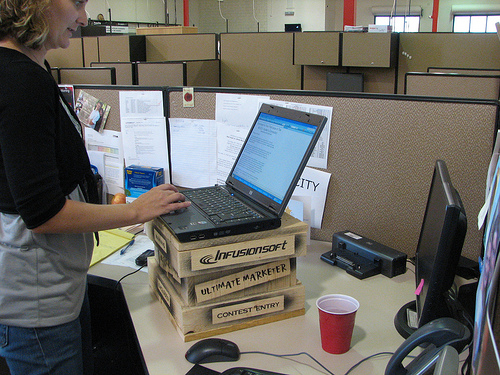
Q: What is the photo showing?
A: It is showing an office.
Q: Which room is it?
A: It is an office.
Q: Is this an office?
A: Yes, it is an office.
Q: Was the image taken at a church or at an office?
A: It was taken at an office.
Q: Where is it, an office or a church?
A: It is an office.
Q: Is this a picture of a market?
A: No, the picture is showing an office.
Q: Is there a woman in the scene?
A: Yes, there is a woman.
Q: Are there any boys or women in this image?
A: Yes, there is a woman.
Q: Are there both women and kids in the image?
A: No, there is a woman but no children.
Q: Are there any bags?
A: No, there are no bags.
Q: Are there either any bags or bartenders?
A: No, there are no bags or bartenders.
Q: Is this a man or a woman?
A: This is a woman.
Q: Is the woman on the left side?
A: Yes, the woman is on the left of the image.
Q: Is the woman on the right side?
A: No, the woman is on the left of the image.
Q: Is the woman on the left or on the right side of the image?
A: The woman is on the left of the image.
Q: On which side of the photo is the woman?
A: The woman is on the left of the image.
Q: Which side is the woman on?
A: The woman is on the left of the image.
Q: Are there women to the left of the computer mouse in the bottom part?
A: Yes, there is a woman to the left of the mouse.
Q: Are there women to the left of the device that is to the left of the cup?
A: Yes, there is a woman to the left of the mouse.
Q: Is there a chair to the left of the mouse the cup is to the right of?
A: No, there is a woman to the left of the computer mouse.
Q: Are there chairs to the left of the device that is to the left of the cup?
A: No, there is a woman to the left of the computer mouse.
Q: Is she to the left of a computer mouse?
A: Yes, the woman is to the left of a computer mouse.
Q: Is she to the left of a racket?
A: No, the woman is to the left of a computer mouse.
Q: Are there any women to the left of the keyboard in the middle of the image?
A: Yes, there is a woman to the left of the keyboard.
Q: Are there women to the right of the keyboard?
A: No, the woman is to the left of the keyboard.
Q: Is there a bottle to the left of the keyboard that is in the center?
A: No, there is a woman to the left of the keyboard.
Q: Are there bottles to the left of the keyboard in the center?
A: No, there is a woman to the left of the keyboard.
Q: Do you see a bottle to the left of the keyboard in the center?
A: No, there is a woman to the left of the keyboard.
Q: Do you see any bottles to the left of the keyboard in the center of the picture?
A: No, there is a woman to the left of the keyboard.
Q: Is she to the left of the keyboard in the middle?
A: Yes, the woman is to the left of the keyboard.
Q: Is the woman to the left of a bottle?
A: No, the woman is to the left of the keyboard.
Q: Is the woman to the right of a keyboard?
A: No, the woman is to the left of a keyboard.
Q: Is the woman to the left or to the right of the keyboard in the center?
A: The woman is to the left of the keyboard.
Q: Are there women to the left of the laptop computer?
A: Yes, there is a woman to the left of the laptop computer.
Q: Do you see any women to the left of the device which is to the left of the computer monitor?
A: Yes, there is a woman to the left of the laptop computer.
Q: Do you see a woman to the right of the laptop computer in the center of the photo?
A: No, the woman is to the left of the laptop.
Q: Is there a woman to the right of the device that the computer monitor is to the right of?
A: No, the woman is to the left of the laptop.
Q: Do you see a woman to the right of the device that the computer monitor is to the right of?
A: No, the woman is to the left of the laptop.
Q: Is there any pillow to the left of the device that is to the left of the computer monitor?
A: No, there is a woman to the left of the laptop.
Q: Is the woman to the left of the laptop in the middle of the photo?
A: Yes, the woman is to the left of the laptop.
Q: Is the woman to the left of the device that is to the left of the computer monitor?
A: Yes, the woman is to the left of the laptop.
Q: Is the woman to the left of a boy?
A: No, the woman is to the left of the laptop.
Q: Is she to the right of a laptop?
A: No, the woman is to the left of a laptop.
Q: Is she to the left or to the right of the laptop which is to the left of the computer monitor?
A: The woman is to the left of the laptop computer.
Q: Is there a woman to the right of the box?
A: No, the woman is to the left of the box.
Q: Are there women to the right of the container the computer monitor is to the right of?
A: No, the woman is to the left of the box.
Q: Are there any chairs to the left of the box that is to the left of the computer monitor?
A: No, there is a woman to the left of the box.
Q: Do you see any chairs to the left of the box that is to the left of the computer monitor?
A: No, there is a woman to the left of the box.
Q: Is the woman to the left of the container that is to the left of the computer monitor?
A: Yes, the woman is to the left of the box.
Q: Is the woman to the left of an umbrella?
A: No, the woman is to the left of the box.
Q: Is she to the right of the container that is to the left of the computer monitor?
A: No, the woman is to the left of the box.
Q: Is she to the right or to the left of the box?
A: The woman is to the left of the box.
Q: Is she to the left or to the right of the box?
A: The woman is to the left of the box.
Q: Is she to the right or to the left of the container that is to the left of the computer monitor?
A: The woman is to the left of the box.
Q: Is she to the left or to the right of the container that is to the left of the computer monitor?
A: The woman is to the left of the box.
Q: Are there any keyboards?
A: Yes, there is a keyboard.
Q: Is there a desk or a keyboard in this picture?
A: Yes, there is a keyboard.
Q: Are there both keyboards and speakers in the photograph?
A: No, there is a keyboard but no speakers.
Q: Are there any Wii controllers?
A: No, there are no Wii controllers.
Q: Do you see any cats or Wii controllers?
A: No, there are no Wii controllers or cats.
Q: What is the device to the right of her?
A: The device is a keyboard.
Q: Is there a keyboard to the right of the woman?
A: Yes, there is a keyboard to the right of the woman.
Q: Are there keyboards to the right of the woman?
A: Yes, there is a keyboard to the right of the woman.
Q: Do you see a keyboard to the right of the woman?
A: Yes, there is a keyboard to the right of the woman.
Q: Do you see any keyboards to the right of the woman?
A: Yes, there is a keyboard to the right of the woman.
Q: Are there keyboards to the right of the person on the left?
A: Yes, there is a keyboard to the right of the woman.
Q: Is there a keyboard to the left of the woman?
A: No, the keyboard is to the right of the woman.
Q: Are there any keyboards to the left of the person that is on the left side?
A: No, the keyboard is to the right of the woman.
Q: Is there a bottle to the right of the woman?
A: No, there is a keyboard to the right of the woman.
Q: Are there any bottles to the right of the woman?
A: No, there is a keyboard to the right of the woman.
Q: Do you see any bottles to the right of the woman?
A: No, there is a keyboard to the right of the woman.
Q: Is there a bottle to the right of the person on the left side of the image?
A: No, there is a keyboard to the right of the woman.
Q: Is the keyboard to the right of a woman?
A: Yes, the keyboard is to the right of a woman.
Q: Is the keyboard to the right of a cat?
A: No, the keyboard is to the right of a woman.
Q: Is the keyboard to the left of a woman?
A: No, the keyboard is to the right of a woman.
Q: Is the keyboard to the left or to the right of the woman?
A: The keyboard is to the right of the woman.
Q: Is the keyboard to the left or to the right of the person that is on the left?
A: The keyboard is to the right of the woman.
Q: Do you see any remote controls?
A: No, there are no remote controls.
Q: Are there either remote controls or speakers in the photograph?
A: No, there are no remote controls or speakers.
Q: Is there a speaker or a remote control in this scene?
A: No, there are no remote controls or speakers.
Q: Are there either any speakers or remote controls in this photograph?
A: No, there are no remote controls or speakers.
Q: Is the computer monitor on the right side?
A: Yes, the computer monitor is on the right of the image.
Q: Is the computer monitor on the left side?
A: No, the computer monitor is on the right of the image.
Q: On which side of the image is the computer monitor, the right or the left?
A: The computer monitor is on the right of the image.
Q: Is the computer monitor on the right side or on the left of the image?
A: The computer monitor is on the right of the image.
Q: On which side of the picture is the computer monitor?
A: The computer monitor is on the right of the image.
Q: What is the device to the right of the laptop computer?
A: The device is a computer monitor.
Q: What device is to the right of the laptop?
A: The device is a computer monitor.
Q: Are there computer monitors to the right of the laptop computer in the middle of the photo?
A: Yes, there is a computer monitor to the right of the laptop.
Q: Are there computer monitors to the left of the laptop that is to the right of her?
A: No, the computer monitor is to the right of the laptop.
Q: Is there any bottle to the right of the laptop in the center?
A: No, there is a computer monitor to the right of the laptop.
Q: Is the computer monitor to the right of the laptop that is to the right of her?
A: Yes, the computer monitor is to the right of the laptop.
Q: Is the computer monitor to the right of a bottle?
A: No, the computer monitor is to the right of the laptop.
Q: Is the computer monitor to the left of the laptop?
A: No, the computer monitor is to the right of the laptop.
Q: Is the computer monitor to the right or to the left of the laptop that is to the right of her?
A: The computer monitor is to the right of the laptop.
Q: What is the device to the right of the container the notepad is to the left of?
A: The device is a computer monitor.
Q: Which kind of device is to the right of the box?
A: The device is a computer monitor.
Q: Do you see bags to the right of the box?
A: No, there is a computer monitor to the right of the box.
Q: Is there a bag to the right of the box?
A: No, there is a computer monitor to the right of the box.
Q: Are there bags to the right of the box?
A: No, there is a computer monitor to the right of the box.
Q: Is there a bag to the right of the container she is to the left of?
A: No, there is a computer monitor to the right of the box.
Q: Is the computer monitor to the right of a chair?
A: No, the computer monitor is to the right of the box.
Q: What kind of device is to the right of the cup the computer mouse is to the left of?
A: The device is a computer monitor.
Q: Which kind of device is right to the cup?
A: The device is a computer monitor.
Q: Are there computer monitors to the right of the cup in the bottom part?
A: Yes, there is a computer monitor to the right of the cup.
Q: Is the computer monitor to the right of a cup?
A: Yes, the computer monitor is to the right of a cup.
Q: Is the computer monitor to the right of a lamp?
A: No, the computer monitor is to the right of a cup.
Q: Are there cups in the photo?
A: Yes, there is a cup.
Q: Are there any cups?
A: Yes, there is a cup.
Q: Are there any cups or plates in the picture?
A: Yes, there is a cup.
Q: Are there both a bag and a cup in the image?
A: No, there is a cup but no bags.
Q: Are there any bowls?
A: No, there are no bowls.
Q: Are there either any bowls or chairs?
A: No, there are no bowls or chairs.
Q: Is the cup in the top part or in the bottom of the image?
A: The cup is in the bottom of the image.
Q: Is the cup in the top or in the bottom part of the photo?
A: The cup is in the bottom of the image.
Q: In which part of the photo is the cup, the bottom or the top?
A: The cup is in the bottom of the image.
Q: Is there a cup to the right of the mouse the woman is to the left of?
A: Yes, there is a cup to the right of the computer mouse.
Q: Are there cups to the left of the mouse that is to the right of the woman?
A: No, the cup is to the right of the computer mouse.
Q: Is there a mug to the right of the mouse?
A: No, there is a cup to the right of the mouse.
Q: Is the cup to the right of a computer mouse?
A: Yes, the cup is to the right of a computer mouse.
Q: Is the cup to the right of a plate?
A: No, the cup is to the right of a computer mouse.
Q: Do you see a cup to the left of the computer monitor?
A: Yes, there is a cup to the left of the computer monitor.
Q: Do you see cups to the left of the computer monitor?
A: Yes, there is a cup to the left of the computer monitor.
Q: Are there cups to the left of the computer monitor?
A: Yes, there is a cup to the left of the computer monitor.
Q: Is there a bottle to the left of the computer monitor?
A: No, there is a cup to the left of the computer monitor.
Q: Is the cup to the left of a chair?
A: No, the cup is to the left of the computer monitor.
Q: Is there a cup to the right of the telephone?
A: No, the cup is to the left of the telephone.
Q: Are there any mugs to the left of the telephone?
A: No, there is a cup to the left of the telephone.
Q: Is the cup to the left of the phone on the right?
A: Yes, the cup is to the left of the telephone.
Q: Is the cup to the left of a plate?
A: No, the cup is to the left of the telephone.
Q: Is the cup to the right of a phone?
A: No, the cup is to the left of a phone.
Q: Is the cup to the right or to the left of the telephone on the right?
A: The cup is to the left of the phone.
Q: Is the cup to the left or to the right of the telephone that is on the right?
A: The cup is to the left of the phone.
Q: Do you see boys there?
A: No, there are no boys.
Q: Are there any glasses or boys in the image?
A: No, there are no boys or glasses.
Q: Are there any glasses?
A: No, there are no glasses.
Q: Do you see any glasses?
A: No, there are no glasses.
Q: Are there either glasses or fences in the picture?
A: No, there are no glasses or fences.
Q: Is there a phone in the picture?
A: Yes, there is a phone.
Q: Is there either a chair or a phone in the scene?
A: Yes, there is a phone.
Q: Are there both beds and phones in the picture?
A: No, there is a phone but no beds.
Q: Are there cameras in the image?
A: No, there are no cameras.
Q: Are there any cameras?
A: No, there are no cameras.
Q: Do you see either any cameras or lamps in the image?
A: No, there are no cameras or lamps.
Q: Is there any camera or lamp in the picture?
A: No, there are no cameras or lamps.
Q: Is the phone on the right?
A: Yes, the phone is on the right of the image.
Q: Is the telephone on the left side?
A: No, the telephone is on the right of the image.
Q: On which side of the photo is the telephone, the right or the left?
A: The telephone is on the right of the image.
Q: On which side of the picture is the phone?
A: The phone is on the right of the image.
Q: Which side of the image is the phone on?
A: The phone is on the right of the image.